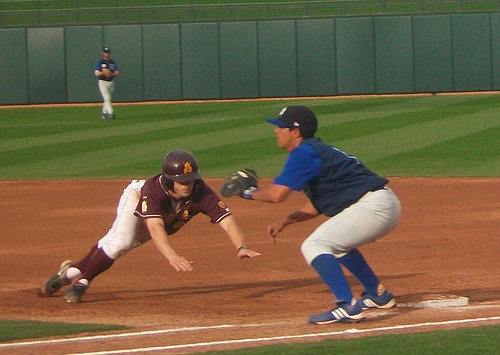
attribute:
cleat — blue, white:
[352, 288, 399, 313]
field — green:
[9, 97, 497, 352]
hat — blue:
[245, 107, 339, 144]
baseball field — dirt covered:
[0, 93, 497, 351]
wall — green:
[9, 31, 495, 88]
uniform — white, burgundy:
[96, 165, 235, 262]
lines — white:
[0, 303, 499, 353]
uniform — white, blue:
[190, 92, 430, 330]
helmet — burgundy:
[132, 142, 202, 203]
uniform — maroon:
[62, 151, 232, 285]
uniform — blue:
[268, 104, 404, 298]